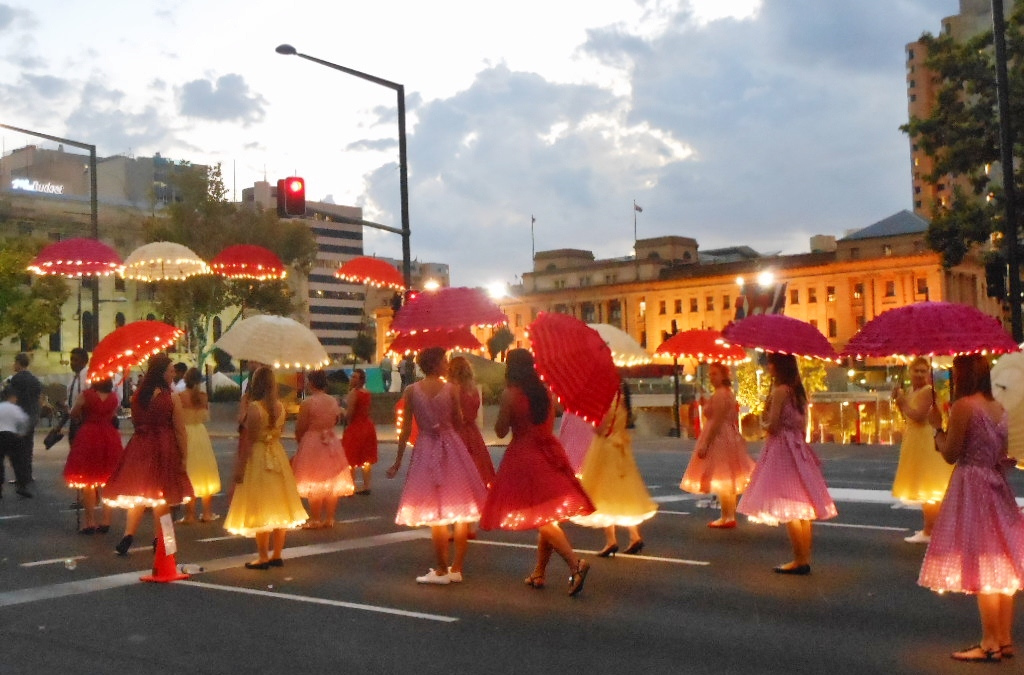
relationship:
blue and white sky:
[714, 48, 795, 123] [456, 3, 630, 139]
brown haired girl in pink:
[780, 360, 795, 376] [770, 447, 804, 491]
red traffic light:
[292, 183, 299, 193] [280, 177, 308, 219]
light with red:
[280, 177, 308, 219] [292, 183, 299, 193]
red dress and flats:
[516, 454, 561, 479] [570, 559, 593, 601]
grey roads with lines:
[100, 611, 179, 661] [20, 555, 54, 573]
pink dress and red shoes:
[770, 447, 804, 491] [710, 511, 744, 529]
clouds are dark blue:
[87, 74, 267, 144] [714, 48, 795, 123]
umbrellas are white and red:
[28, 231, 286, 279] [292, 183, 299, 193]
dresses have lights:
[228, 391, 379, 536] [414, 507, 540, 529]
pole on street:
[398, 79, 411, 262] [644, 568, 733, 649]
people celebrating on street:
[146, 325, 644, 549] [644, 568, 733, 649]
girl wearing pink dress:
[925, 362, 1019, 649] [943, 398, 1022, 599]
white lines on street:
[661, 543, 711, 577] [644, 568, 733, 649]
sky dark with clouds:
[456, 3, 630, 139] [87, 74, 267, 144]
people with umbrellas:
[146, 325, 644, 549] [28, 231, 286, 279]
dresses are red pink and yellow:
[228, 391, 379, 536] [239, 395, 301, 533]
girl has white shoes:
[232, 366, 291, 555] [420, 564, 464, 585]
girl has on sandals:
[232, 366, 291, 555] [560, 561, 591, 603]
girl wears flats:
[232, 366, 291, 555] [570, 559, 593, 601]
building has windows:
[635, 256, 767, 315] [648, 294, 720, 320]